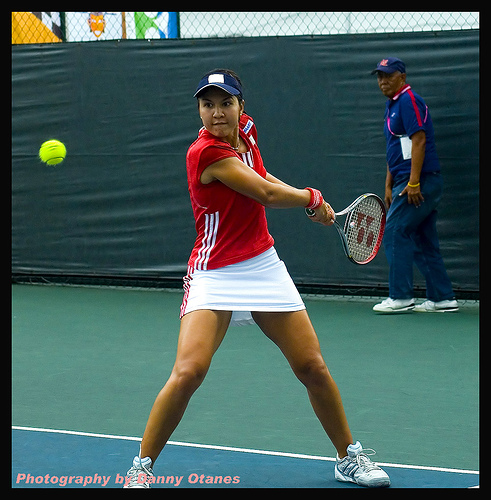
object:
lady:
[121, 66, 391, 497]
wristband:
[304, 187, 323, 210]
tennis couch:
[365, 54, 433, 126]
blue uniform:
[383, 84, 441, 179]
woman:
[122, 69, 389, 488]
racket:
[304, 193, 387, 265]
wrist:
[408, 179, 420, 185]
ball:
[38, 139, 67, 167]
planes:
[185, 67, 384, 266]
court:
[8, 27, 480, 488]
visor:
[192, 82, 239, 97]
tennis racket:
[304, 192, 386, 265]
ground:
[11, 283, 479, 490]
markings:
[11, 422, 479, 475]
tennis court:
[11, 30, 479, 488]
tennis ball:
[38, 139, 68, 166]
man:
[370, 56, 459, 312]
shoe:
[411, 300, 459, 313]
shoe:
[334, 441, 390, 488]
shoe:
[122, 456, 152, 490]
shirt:
[186, 113, 274, 272]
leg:
[122, 309, 233, 489]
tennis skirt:
[179, 244, 306, 326]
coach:
[370, 57, 459, 313]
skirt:
[179, 245, 307, 326]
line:
[10, 424, 480, 473]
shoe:
[372, 297, 415, 312]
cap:
[192, 72, 243, 98]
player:
[121, 68, 390, 490]